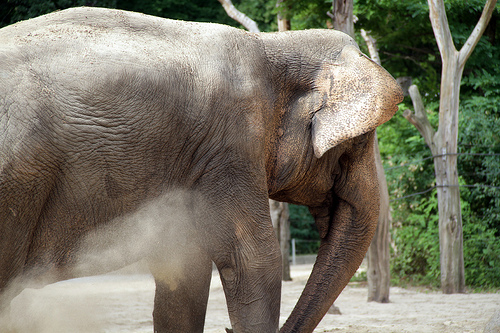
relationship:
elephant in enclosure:
[0, 5, 407, 332] [3, 1, 498, 329]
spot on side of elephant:
[99, 148, 155, 198] [251, 17, 420, 267]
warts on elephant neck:
[264, 96, 289, 151] [256, 33, 406, 213]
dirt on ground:
[366, 303, 426, 317] [327, 132, 363, 178]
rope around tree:
[414, 154, 474, 196] [407, 0, 499, 297]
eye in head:
[356, 130, 375, 165] [231, 11, 441, 258]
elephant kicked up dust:
[0, 5, 407, 332] [2, 187, 219, 330]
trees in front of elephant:
[326, 0, 476, 302] [0, 5, 407, 332]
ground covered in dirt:
[19, 249, 497, 331] [7, 254, 498, 331]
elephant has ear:
[0, 5, 407, 332] [305, 40, 405, 157]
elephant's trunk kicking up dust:
[274, 156, 379, 331] [396, 287, 456, 331]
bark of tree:
[408, 0, 498, 294] [397, 4, 492, 299]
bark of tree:
[210, 0, 290, 331] [219, 1, 389, 299]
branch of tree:
[398, 81, 434, 150] [424, 15, 486, 310]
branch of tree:
[457, 0, 498, 60] [398, 3, 498, 277]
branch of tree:
[401, 84, 434, 150] [407, 0, 499, 297]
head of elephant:
[266, 25, 404, 228] [0, 5, 407, 332]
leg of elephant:
[215, 220, 286, 331] [0, 5, 407, 332]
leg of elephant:
[148, 238, 215, 333] [0, 5, 407, 332]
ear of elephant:
[299, 34, 411, 166] [0, 5, 407, 332]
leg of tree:
[353, 149, 401, 304] [327, 0, 392, 302]